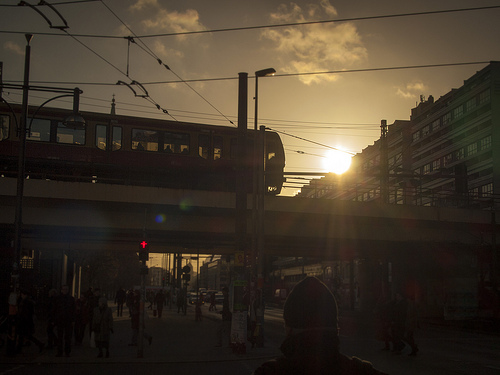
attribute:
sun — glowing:
[312, 131, 368, 189]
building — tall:
[385, 64, 497, 365]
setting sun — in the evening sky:
[318, 142, 353, 177]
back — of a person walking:
[256, 277, 376, 373]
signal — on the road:
[135, 230, 152, 264]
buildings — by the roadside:
[280, 78, 482, 320]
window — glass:
[155, 130, 182, 160]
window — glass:
[133, 132, 160, 161]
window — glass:
[113, 128, 129, 157]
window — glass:
[88, 123, 108, 155]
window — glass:
[52, 126, 79, 149]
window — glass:
[4, 99, 285, 208]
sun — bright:
[317, 141, 351, 177]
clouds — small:
[117, 6, 444, 131]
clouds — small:
[117, 4, 451, 144]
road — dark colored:
[184, 294, 393, 374]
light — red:
[124, 230, 150, 254]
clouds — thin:
[227, 3, 398, 103]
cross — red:
[133, 230, 157, 261]